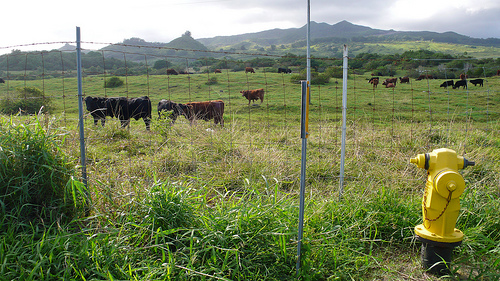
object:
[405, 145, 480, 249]
hydrant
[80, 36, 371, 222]
fence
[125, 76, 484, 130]
field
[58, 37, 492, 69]
barbed wire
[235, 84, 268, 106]
cow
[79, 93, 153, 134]
cows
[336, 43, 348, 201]
pole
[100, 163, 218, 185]
grass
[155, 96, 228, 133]
cows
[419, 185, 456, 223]
chain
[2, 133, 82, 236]
bushes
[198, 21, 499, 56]
mountains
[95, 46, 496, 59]
edge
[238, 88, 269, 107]
body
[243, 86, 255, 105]
side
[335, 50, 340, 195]
edge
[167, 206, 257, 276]
grass